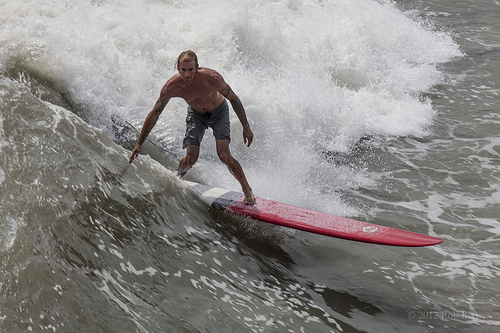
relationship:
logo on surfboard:
[362, 221, 378, 235] [179, 178, 443, 256]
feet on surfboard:
[242, 191, 260, 205] [179, 178, 443, 256]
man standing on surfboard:
[128, 44, 266, 208] [179, 178, 443, 256]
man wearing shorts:
[128, 44, 266, 208] [178, 103, 232, 146]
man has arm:
[128, 44, 266, 208] [211, 70, 262, 144]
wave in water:
[11, 3, 463, 206] [1, 1, 498, 331]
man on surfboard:
[128, 44, 266, 208] [179, 178, 443, 256]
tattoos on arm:
[222, 86, 249, 122] [211, 70, 262, 144]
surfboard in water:
[179, 178, 443, 256] [1, 1, 498, 331]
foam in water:
[30, 16, 426, 208] [1, 1, 498, 331]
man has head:
[128, 44, 266, 208] [172, 49, 202, 82]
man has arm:
[128, 44, 266, 208] [125, 82, 178, 164]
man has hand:
[128, 44, 266, 208] [241, 124, 258, 148]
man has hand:
[128, 44, 266, 208] [129, 143, 142, 161]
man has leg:
[128, 44, 266, 208] [212, 108, 258, 205]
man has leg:
[128, 44, 266, 208] [175, 115, 206, 184]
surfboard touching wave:
[179, 178, 443, 256] [11, 3, 463, 206]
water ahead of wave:
[1, 1, 498, 331] [11, 3, 463, 206]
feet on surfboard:
[171, 171, 261, 205] [179, 178, 443, 256]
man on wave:
[128, 44, 266, 208] [11, 3, 463, 206]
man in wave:
[128, 44, 266, 208] [11, 3, 463, 206]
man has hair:
[128, 44, 266, 208] [177, 48, 199, 65]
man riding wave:
[128, 44, 266, 208] [11, 3, 463, 206]